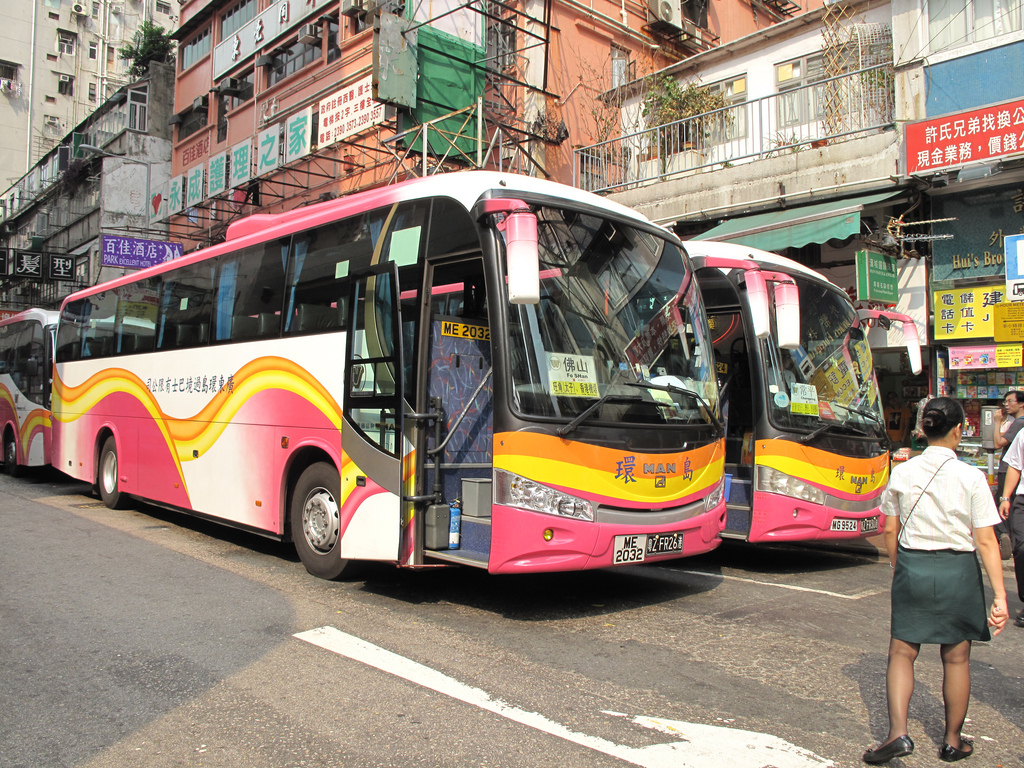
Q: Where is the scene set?
A: On the street.